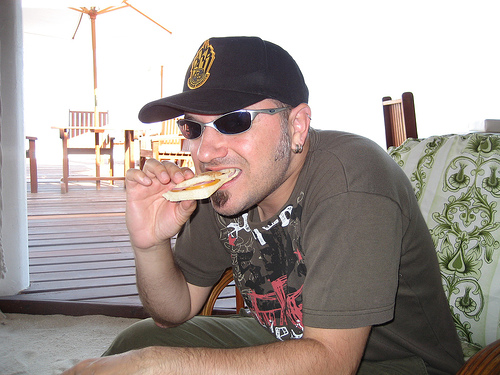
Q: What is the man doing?
A: Eating.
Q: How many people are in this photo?
A: One.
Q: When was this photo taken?
A: Daytime.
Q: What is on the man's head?
A: A baseball cap.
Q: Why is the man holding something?
A: So that he can eat.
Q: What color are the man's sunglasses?
A: Silver.